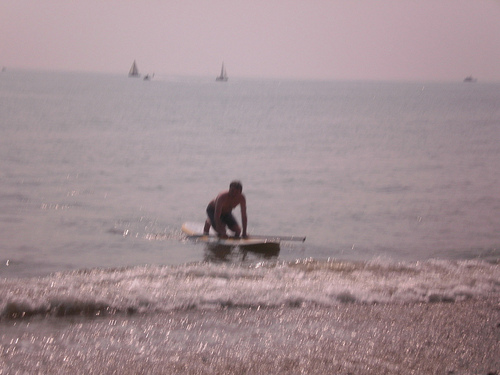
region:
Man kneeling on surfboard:
[182, 179, 285, 251]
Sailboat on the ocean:
[215, 61, 229, 85]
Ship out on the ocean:
[464, 71, 480, 81]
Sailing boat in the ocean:
[130, 58, 142, 78]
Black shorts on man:
[202, 200, 235, 225]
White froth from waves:
[9, 270, 499, 305]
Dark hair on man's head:
[230, 178, 245, 190]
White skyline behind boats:
[3, 2, 497, 84]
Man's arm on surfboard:
[238, 196, 250, 233]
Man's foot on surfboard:
[204, 222, 211, 235]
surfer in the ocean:
[161, 170, 306, 267]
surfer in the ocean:
[157, 158, 324, 266]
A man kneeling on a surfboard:
[165, 160, 312, 289]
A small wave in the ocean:
[88, 246, 469, 309]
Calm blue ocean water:
[216, 128, 441, 172]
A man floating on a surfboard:
[168, 173, 321, 261]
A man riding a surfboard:
[164, 165, 347, 265]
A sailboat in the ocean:
[202, 58, 244, 91]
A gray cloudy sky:
[253, 12, 428, 64]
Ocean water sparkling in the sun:
[103, 207, 173, 255]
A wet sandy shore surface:
[218, 315, 494, 372]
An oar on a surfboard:
[179, 225, 319, 248]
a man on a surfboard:
[156, 149, 299, 276]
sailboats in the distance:
[102, 42, 256, 99]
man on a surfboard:
[169, 176, 319, 277]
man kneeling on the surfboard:
[162, 175, 306, 265]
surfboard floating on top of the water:
[178, 215, 288, 262]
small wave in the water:
[3, 261, 493, 372]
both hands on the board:
[208, 215, 263, 242]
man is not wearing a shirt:
[187, 176, 276, 256]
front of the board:
[245, 235, 284, 250]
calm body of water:
[1, 62, 498, 372]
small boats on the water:
[116, 58, 240, 88]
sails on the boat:
[123, 58, 143, 79]